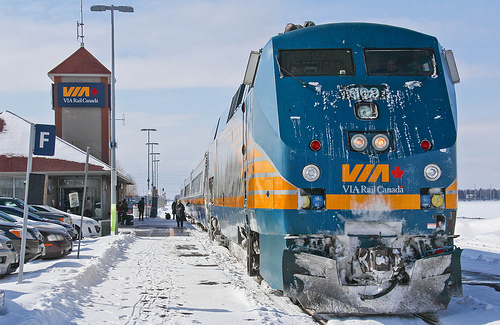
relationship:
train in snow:
[175, 9, 460, 319] [3, 188, 500, 324]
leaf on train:
[390, 164, 404, 181] [175, 9, 460, 319]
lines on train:
[178, 111, 463, 231] [175, 9, 460, 319]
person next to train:
[173, 200, 189, 225] [175, 9, 460, 319]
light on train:
[308, 136, 322, 153] [175, 9, 460, 319]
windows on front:
[275, 46, 446, 83] [266, 14, 483, 193]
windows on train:
[275, 46, 446, 83] [175, 9, 460, 319]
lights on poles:
[90, 2, 185, 163] [108, 3, 162, 236]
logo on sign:
[64, 83, 99, 97] [52, 83, 107, 109]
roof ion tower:
[47, 44, 121, 75] [37, 37, 137, 170]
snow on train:
[3, 188, 500, 324] [175, 9, 460, 319]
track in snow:
[114, 243, 219, 324] [3, 188, 500, 324]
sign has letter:
[28, 120, 61, 152] [38, 130, 48, 152]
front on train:
[266, 14, 483, 193] [175, 9, 460, 319]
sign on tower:
[52, 83, 107, 109] [37, 37, 137, 170]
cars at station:
[0, 189, 105, 291] [0, 23, 134, 241]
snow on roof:
[0, 106, 110, 168] [0, 94, 117, 181]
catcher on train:
[265, 225, 476, 321] [175, 9, 460, 319]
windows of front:
[275, 46, 446, 83] [266, 14, 483, 193]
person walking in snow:
[171, 199, 187, 230] [10, 208, 296, 321]